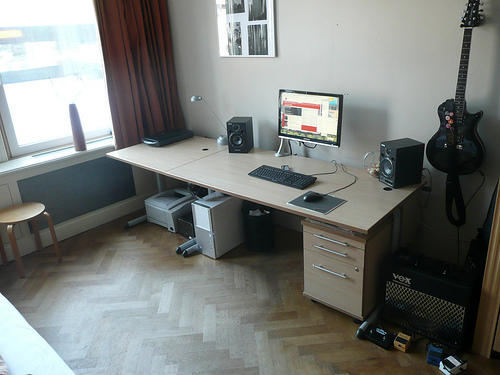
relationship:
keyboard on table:
[248, 156, 314, 191] [191, 144, 353, 233]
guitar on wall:
[428, 1, 483, 197] [286, 7, 427, 141]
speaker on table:
[215, 111, 259, 158] [191, 144, 353, 233]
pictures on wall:
[209, 1, 284, 63] [286, 7, 427, 141]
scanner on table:
[132, 119, 195, 154] [191, 144, 353, 233]